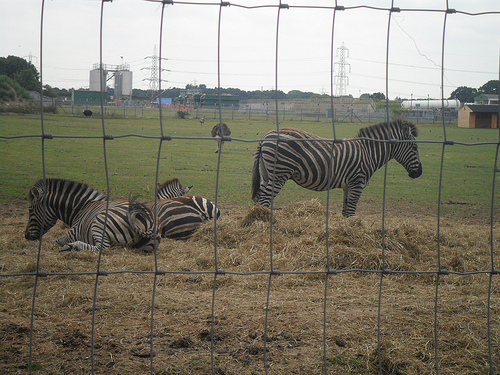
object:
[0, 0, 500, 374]
photograph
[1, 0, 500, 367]
zoo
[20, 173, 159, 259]
zebra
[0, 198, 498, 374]
hay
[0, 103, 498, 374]
field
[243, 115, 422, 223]
zebra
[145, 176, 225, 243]
zebra